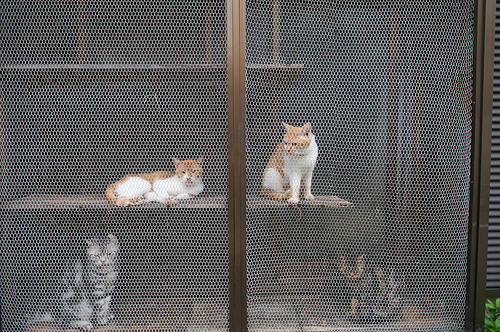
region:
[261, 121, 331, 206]
small cat sitting behind grate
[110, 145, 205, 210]
small cat sitting behind grate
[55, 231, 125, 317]
small cat sitting behind gratesmall cat sitting behind grate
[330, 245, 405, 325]
small cat sitting behind grate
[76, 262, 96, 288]
gray fur on small cat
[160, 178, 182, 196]
white fur on cat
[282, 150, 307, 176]
white fur on cat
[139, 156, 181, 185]
tan fur on cat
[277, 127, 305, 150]
tan fur on cat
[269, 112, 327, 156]
head of a cat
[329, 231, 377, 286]
head of a cat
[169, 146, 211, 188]
head of a cat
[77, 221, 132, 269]
head of a cat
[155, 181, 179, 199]
leg of a cat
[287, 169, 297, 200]
leg of a cat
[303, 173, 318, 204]
leg of a cat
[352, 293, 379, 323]
leg of a cat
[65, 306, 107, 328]
leg of a cat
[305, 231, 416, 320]
the cat is brown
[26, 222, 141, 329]
the cat is grey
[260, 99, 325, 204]
cat is orange and white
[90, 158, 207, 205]
orange and white cat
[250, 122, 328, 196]
the cat is sitting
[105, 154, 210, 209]
the cat is laying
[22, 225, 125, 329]
the cat is sitting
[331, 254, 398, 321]
the cat is sitting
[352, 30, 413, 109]
the netting of fence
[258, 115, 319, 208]
orange and white seated on shelf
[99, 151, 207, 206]
orange and white cat lying on shelf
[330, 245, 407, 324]
tabby cat seated on ground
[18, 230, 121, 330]
black and grey cat seated on ground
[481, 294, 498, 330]
bush to right of cage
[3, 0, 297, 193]
window inside cage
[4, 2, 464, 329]
chicken wire enclosing pet cage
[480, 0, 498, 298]
corrugated metal to right of cage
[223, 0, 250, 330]
wooden frame bar between chicken wire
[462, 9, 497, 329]
wooden frame bar to right of chicken wire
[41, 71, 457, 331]
four cats in photo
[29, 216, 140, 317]
gray and black cat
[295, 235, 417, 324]
cat sitting down on ground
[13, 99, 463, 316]
four cats in a cage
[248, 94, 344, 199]
orange and white cat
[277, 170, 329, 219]
front paws of cat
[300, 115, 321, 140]
ear of the cat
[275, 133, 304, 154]
eyes of the cat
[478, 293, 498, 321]
leaves next to cage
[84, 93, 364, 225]
two orange and white cats